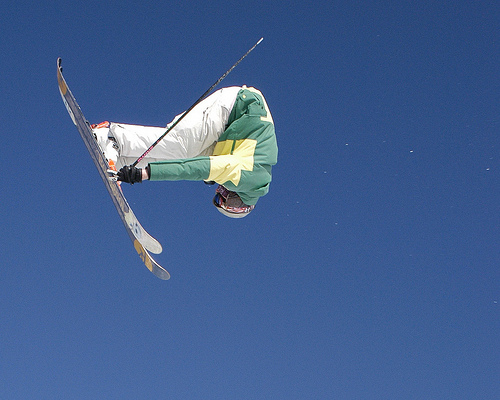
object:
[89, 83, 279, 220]
man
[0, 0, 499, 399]
air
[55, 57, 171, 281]
ski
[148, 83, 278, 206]
jacket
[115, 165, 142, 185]
glove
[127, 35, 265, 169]
pole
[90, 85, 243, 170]
pants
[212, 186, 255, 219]
head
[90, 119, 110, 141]
shoe